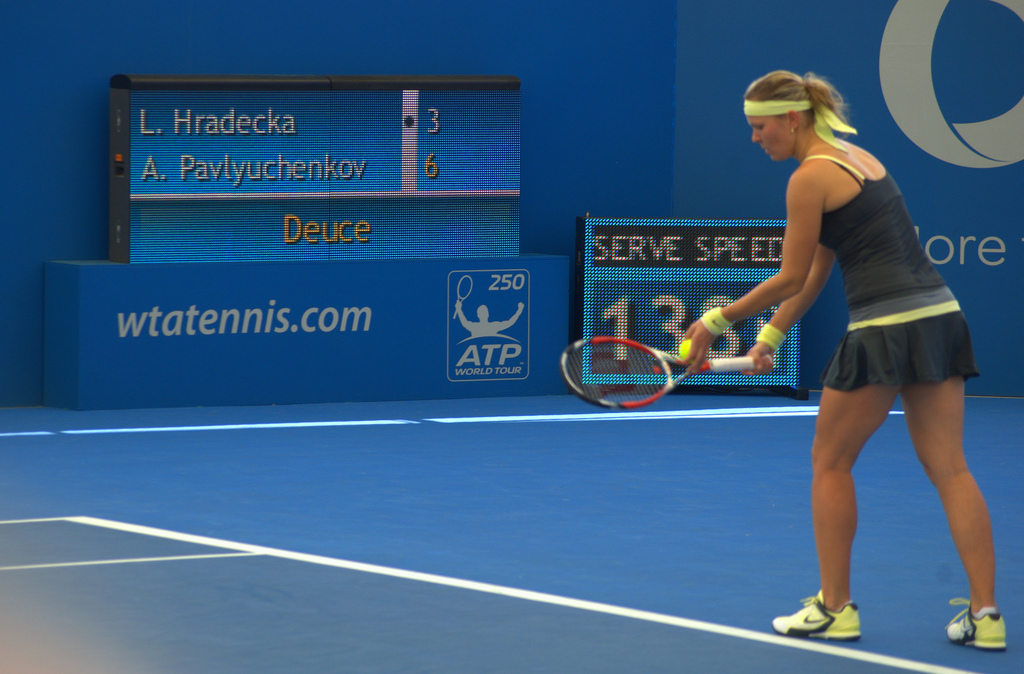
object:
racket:
[559, 335, 773, 409]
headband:
[756, 322, 786, 349]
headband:
[744, 100, 813, 117]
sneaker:
[772, 590, 862, 642]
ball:
[679, 338, 706, 363]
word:
[284, 214, 374, 244]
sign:
[570, 210, 809, 399]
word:
[592, 234, 787, 262]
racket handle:
[707, 354, 772, 372]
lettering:
[117, 300, 372, 337]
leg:
[904, 377, 995, 615]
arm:
[673, 177, 837, 374]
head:
[744, 71, 848, 162]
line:
[63, 514, 970, 674]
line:
[0, 551, 273, 571]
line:
[0, 515, 93, 524]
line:
[0, 405, 904, 438]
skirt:
[819, 283, 981, 391]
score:
[142, 106, 441, 188]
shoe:
[945, 597, 1006, 651]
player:
[679, 69, 1007, 651]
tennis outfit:
[802, 155, 978, 391]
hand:
[740, 346, 772, 375]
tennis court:
[0, 410, 1022, 665]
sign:
[107, 75, 521, 264]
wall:
[0, 0, 1024, 410]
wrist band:
[699, 307, 732, 337]